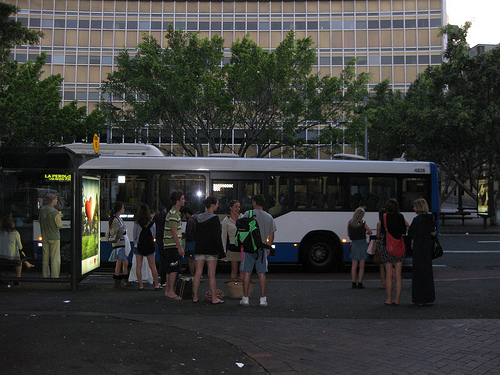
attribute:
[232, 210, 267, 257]
backpack — black, green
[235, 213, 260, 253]
bag — black, green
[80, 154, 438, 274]
bus — blue, white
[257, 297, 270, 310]
sneaker — white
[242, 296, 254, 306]
sneaker — white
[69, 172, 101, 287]
sign — lit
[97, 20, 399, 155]
tree — large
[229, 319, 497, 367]
pattern — cobblestone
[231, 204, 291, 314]
man — black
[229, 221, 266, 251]
backpack — green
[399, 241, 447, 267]
purse — black